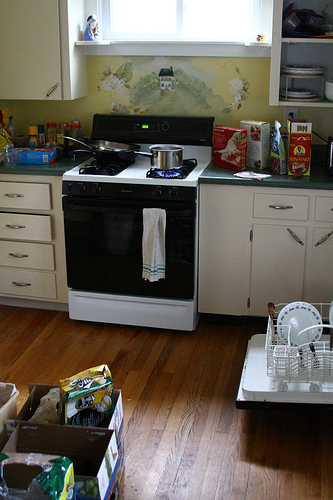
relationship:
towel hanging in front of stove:
[141, 206, 167, 283] [61, 124, 222, 239]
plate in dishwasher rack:
[276, 300, 323, 348] [262, 302, 332, 385]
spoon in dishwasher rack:
[266, 300, 276, 332] [262, 302, 332, 385]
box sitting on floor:
[7, 379, 125, 461] [1, 304, 329, 499]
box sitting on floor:
[0, 423, 121, 499] [1, 304, 329, 499]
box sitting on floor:
[1, 450, 78, 498] [1, 304, 329, 499]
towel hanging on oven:
[137, 196, 174, 285] [60, 112, 213, 334]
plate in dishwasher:
[276, 300, 323, 348] [234, 300, 331, 412]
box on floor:
[15, 382, 126, 483] [1, 304, 329, 499]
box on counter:
[285, 120, 310, 177] [199, 157, 331, 188]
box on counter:
[238, 118, 271, 173] [199, 157, 331, 188]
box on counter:
[211, 124, 246, 169] [199, 157, 331, 188]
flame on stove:
[156, 168, 181, 178] [86, 133, 205, 241]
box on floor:
[58, 363, 113, 424] [1, 304, 329, 499]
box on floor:
[1, 423, 121, 496] [1, 304, 329, 499]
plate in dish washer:
[276, 300, 323, 348] [235, 300, 332, 409]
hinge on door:
[248, 226, 254, 243] [244, 210, 327, 345]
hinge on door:
[247, 297, 251, 308] [244, 210, 327, 345]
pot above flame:
[127, 141, 184, 169] [156, 168, 180, 175]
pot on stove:
[127, 141, 184, 169] [61, 143, 211, 188]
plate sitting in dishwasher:
[278, 309, 315, 346] [262, 328, 331, 381]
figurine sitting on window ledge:
[79, 13, 100, 42] [67, 31, 274, 56]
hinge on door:
[249, 230, 253, 242] [247, 223, 306, 315]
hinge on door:
[247, 296, 252, 308] [247, 223, 306, 315]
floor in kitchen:
[1, 304, 329, 499] [0, 0, 332, 499]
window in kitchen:
[101, 0, 261, 39] [0, 0, 332, 499]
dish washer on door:
[230, 294, 332, 414] [231, 292, 322, 422]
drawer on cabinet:
[0, 181, 51, 211] [267, 2, 331, 106]